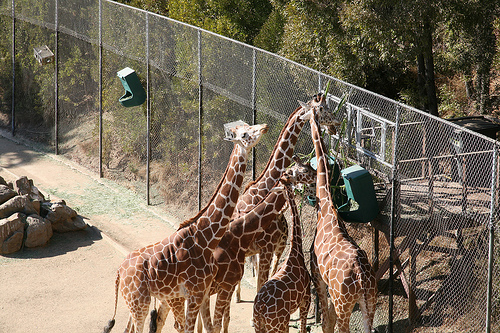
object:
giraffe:
[148, 154, 315, 332]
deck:
[390, 124, 499, 231]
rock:
[3, 191, 37, 221]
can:
[447, 111, 493, 188]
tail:
[105, 275, 125, 332]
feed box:
[304, 154, 346, 212]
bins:
[336, 164, 379, 224]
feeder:
[112, 61, 152, 110]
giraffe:
[100, 119, 269, 332]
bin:
[116, 66, 146, 109]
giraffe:
[233, 93, 336, 304]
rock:
[22, 214, 59, 247]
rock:
[47, 204, 89, 236]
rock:
[16, 175, 38, 190]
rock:
[0, 179, 22, 198]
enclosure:
[3, 6, 498, 332]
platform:
[348, 75, 484, 329]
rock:
[0, 216, 24, 255]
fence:
[1, 4, 499, 331]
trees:
[297, 12, 454, 65]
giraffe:
[295, 95, 376, 332]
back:
[317, 214, 367, 260]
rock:
[0, 191, 40, 216]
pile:
[0, 173, 90, 256]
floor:
[0, 134, 309, 332]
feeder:
[336, 159, 391, 222]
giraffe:
[253, 174, 314, 333]